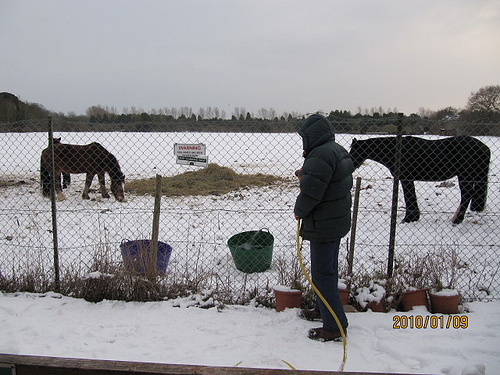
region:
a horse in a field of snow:
[23, 130, 134, 207]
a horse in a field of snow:
[346, 128, 493, 229]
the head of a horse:
[346, 134, 366, 172]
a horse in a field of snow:
[107, 165, 128, 206]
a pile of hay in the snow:
[141, 161, 270, 203]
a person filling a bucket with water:
[228, 105, 371, 373]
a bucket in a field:
[113, 230, 178, 274]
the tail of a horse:
[468, 145, 494, 217]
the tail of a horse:
[35, 150, 54, 202]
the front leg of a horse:
[79, 168, 96, 204]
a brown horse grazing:
[42, 141, 128, 206]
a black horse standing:
[345, 135, 492, 227]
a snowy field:
[2, 133, 499, 288]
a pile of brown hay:
[127, 163, 279, 198]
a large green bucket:
[227, 228, 273, 271]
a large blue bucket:
[118, 237, 170, 273]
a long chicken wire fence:
[3, 117, 499, 296]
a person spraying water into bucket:
[227, 115, 354, 373]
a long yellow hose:
[296, 219, 349, 371]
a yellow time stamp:
[390, 313, 468, 330]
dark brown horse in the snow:
[26, 134, 136, 212]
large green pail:
[222, 227, 278, 277]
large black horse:
[349, 129, 499, 224]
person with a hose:
[273, 111, 363, 373]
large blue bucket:
[114, 237, 179, 274]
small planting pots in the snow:
[273, 279, 480, 317]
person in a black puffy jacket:
[275, 114, 357, 354]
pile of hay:
[121, 154, 283, 201]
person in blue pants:
[279, 102, 348, 362]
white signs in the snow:
[168, 139, 209, 175]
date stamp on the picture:
[381, 310, 472, 335]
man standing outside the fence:
[286, 110, 353, 351]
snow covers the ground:
[79, 305, 212, 369]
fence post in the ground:
[41, 115, 64, 309]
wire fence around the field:
[60, 130, 105, 285]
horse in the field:
[340, 130, 490, 227]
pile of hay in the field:
[161, 161, 242, 201]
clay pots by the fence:
[354, 274, 463, 313]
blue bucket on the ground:
[114, 240, 181, 275]